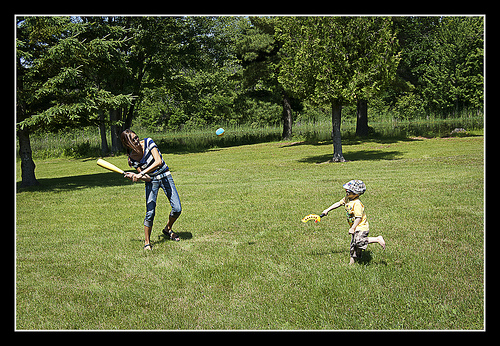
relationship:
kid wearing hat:
[319, 177, 387, 266] [343, 177, 367, 197]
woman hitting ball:
[118, 127, 183, 252] [214, 127, 225, 138]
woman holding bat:
[118, 127, 183, 252] [95, 158, 140, 184]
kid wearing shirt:
[319, 177, 387, 266] [340, 197, 369, 232]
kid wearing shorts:
[319, 177, 387, 266] [348, 230, 369, 260]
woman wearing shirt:
[118, 127, 183, 252] [128, 139, 170, 181]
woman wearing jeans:
[118, 127, 183, 252] [141, 175, 182, 227]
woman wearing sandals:
[118, 127, 183, 252] [141, 228, 179, 253]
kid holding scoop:
[319, 177, 387, 266] [299, 211, 329, 225]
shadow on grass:
[298, 146, 401, 165] [17, 137, 484, 329]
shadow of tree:
[298, 146, 401, 165] [273, 17, 399, 165]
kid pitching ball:
[319, 177, 387, 266] [214, 127, 225, 138]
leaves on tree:
[276, 17, 398, 107] [273, 17, 399, 165]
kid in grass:
[319, 177, 387, 266] [17, 137, 484, 329]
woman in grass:
[118, 127, 183, 252] [17, 137, 484, 329]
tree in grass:
[273, 17, 399, 165] [17, 137, 484, 329]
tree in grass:
[17, 17, 137, 188] [17, 137, 484, 329]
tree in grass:
[238, 18, 305, 140] [17, 137, 484, 329]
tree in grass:
[92, 16, 201, 156] [17, 137, 484, 329]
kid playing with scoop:
[319, 177, 387, 266] [299, 211, 329, 225]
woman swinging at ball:
[118, 127, 183, 252] [214, 127, 225, 138]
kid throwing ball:
[319, 177, 387, 266] [214, 127, 225, 138]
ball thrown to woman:
[214, 127, 225, 138] [118, 127, 183, 252]